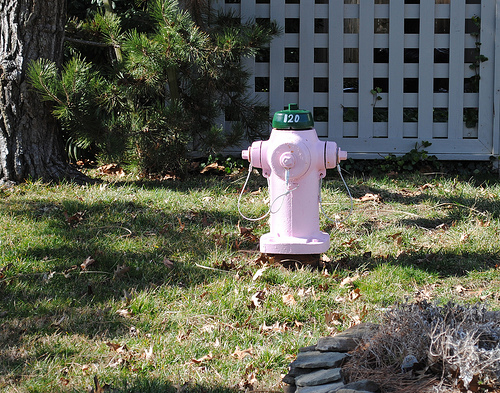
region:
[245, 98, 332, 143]
Fire hydrant number 120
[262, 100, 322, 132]
Green top on fire hydrant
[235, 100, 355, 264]
Green and pink fire hydrant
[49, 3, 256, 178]
Small pine tree behind the hydrant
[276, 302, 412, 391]
Rocks laid out in a circular pattern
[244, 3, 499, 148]
White painted wood fence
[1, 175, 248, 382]
Shadow cast on the ground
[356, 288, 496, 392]
A bunch of dead plants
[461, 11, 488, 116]
Plants coming through the fence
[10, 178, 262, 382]
Fallen leaves scattered in the grass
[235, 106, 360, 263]
fire hydrant in the grass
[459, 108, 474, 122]
space in the fence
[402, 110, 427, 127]
space in the fence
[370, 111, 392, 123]
space in the fence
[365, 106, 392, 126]
space in the fence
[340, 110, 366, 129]
space in the fence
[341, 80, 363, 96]
space in the fence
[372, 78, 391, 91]
space in the fence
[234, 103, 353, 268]
pink fire hydrant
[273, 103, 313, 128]
green cap of fire hydrant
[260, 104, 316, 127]
white numbers of green cap of pink fire hydrant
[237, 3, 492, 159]
white lattice fence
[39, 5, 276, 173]
small pine tree or bush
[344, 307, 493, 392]
dead flower garden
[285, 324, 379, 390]
rock edging on dead flower garden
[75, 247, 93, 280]
brown leaf off of tree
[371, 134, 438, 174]
weed growing by fence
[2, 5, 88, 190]
tree trunk of a tree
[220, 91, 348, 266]
a pink and green fire hydrant.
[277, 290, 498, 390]
a patch of dry grass.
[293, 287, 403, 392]
a stone enclosure.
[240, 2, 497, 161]
a wall near a fire hydrant.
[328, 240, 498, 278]
a shadow near a fire hydrant.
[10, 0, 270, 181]
a lush green leafy plant.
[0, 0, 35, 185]
a tree near a bush.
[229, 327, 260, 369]
a leaf on the grass.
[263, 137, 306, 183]
a valve on a fire hydrant.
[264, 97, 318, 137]
a green cap.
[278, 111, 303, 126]
120 written on fire hydrant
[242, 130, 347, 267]
Pink base of fire hydrant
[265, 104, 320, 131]
Green top of fire hydrant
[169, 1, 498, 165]
White wooden fence behind hydrant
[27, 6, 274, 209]
Green bush at base of tree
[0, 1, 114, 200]
Grayish brown trunk of tree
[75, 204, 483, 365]
brown leaves on ground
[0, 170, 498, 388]
Green grass on ground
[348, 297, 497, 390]
brown dead plants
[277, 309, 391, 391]
Stones around brown dead plants